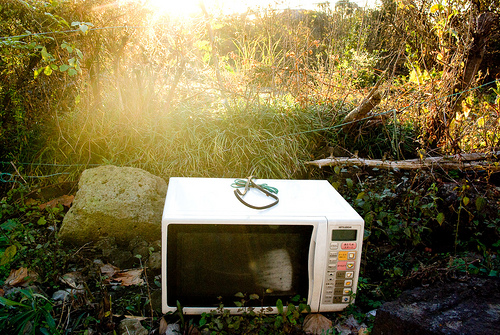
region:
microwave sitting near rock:
[136, 146, 409, 316]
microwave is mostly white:
[155, 169, 355, 333]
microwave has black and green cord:
[227, 156, 283, 226]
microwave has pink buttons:
[331, 239, 353, 272]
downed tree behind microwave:
[289, 143, 499, 204]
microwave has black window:
[160, 223, 316, 311]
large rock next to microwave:
[63, 169, 165, 240]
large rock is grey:
[68, 144, 164, 236]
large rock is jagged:
[51, 156, 183, 251]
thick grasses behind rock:
[10, 93, 327, 155]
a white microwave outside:
[97, 128, 396, 334]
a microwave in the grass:
[128, 129, 400, 334]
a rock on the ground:
[19, 136, 233, 300]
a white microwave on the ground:
[49, 131, 424, 334]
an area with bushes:
[57, 16, 417, 153]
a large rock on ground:
[43, 122, 495, 318]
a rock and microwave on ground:
[12, 86, 460, 334]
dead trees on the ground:
[347, 7, 486, 284]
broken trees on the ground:
[321, 49, 499, 244]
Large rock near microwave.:
[73, 179, 153, 244]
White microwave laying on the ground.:
[151, 179, 324, 331]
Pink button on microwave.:
[343, 243, 365, 258]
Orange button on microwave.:
[336, 247, 353, 272]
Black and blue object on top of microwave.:
[235, 180, 269, 243]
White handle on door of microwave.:
[305, 233, 336, 330]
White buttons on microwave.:
[328, 275, 329, 305]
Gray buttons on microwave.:
[333, 273, 343, 309]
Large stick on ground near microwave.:
[331, 147, 442, 214]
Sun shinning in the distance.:
[108, 40, 278, 137]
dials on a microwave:
[326, 228, 357, 307]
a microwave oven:
[138, 164, 377, 322]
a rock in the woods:
[67, 157, 171, 250]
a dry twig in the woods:
[302, 143, 497, 175]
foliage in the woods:
[17, 20, 95, 101]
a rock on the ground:
[298, 312, 336, 333]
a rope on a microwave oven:
[226, 171, 293, 215]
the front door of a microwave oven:
[166, 221, 329, 313]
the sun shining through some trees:
[127, 6, 289, 95]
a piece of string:
[9, 143, 96, 175]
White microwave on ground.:
[150, 172, 331, 288]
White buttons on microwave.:
[327, 253, 333, 305]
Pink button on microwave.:
[333, 260, 342, 270]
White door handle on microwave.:
[302, 236, 319, 328]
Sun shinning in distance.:
[139, 13, 274, 165]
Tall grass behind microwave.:
[143, 106, 298, 176]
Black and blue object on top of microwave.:
[228, 172, 280, 224]